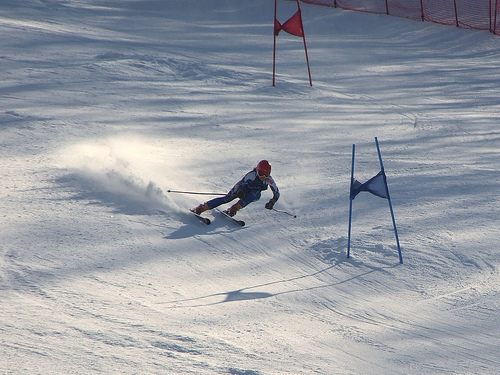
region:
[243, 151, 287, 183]
face of the person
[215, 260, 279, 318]
shadow on the ice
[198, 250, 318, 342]
shadow of the stand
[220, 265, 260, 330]
shadow of the flag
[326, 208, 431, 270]
two sticks in ice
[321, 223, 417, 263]
two poles in ice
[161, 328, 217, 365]
a small whole in ice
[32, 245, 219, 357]
clear view of ice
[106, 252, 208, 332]
sun shine on ice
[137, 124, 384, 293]
a man skating in ice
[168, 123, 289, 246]
A persson is skiing.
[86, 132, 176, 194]
Snow splashing in the air.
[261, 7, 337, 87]
A red flag in the snow.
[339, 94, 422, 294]
A blue flag on the snow.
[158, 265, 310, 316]
Reflection in the snow.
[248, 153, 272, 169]
The person is wearing a red helmet.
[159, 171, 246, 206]
The person is holding ski poles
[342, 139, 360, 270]
Pole is blue.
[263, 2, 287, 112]
The pole is red.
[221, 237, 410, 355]
Ski prints in the snow.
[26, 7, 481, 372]
A person is up in the mountains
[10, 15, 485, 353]
A person is doing some snow skiing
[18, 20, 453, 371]
A person is carrying some ski poles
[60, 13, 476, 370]
A person is using some snow skis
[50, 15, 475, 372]
A person is casting a shadow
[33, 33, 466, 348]
A person is wearing a helmet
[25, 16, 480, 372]
A person is going very fast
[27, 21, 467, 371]
A person is having a great time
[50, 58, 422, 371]
A person is out in the sunshine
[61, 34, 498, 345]
A person is enjoying the day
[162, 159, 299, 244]
skiier gets ready to make turn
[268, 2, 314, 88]
flag marks the course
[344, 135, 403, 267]
flag marks the course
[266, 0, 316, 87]
flag tells the skiier where to turn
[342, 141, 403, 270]
flag tells the skier where to turn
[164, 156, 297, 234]
skier holds two ski poles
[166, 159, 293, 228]
skier leans into the turn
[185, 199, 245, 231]
skiis are worn by the skier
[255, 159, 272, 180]
skier wears helmet for safety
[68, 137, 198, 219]
snow is sent flying as the skier makes his turn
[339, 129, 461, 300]
two poles in ice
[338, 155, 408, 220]
blue flat in ice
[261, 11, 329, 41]
red flag in ice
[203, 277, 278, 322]
shadow of the flat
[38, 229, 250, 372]
a clear view of ice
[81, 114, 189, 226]
disturbance in the ice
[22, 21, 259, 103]
a nice view of snow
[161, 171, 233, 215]
a man holding pole